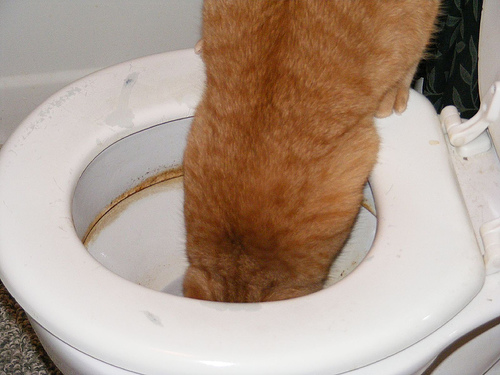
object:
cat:
[182, 0, 442, 303]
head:
[180, 266, 325, 303]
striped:
[297, 12, 382, 123]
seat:
[0, 47, 486, 375]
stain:
[80, 160, 193, 251]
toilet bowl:
[71, 107, 384, 305]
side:
[0, 0, 203, 49]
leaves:
[459, 34, 478, 90]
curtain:
[409, 0, 484, 120]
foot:
[373, 82, 411, 119]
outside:
[423, 315, 499, 373]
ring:
[361, 201, 373, 217]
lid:
[476, 0, 499, 159]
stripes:
[212, 11, 255, 120]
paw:
[194, 37, 204, 56]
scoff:
[104, 72, 144, 133]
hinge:
[440, 80, 500, 148]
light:
[187, 352, 241, 371]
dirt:
[418, 135, 446, 152]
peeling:
[195, 302, 263, 322]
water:
[160, 277, 186, 297]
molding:
[0, 61, 107, 155]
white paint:
[51, 17, 119, 54]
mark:
[61, 108, 388, 313]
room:
[0, 0, 500, 375]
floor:
[0, 329, 42, 375]